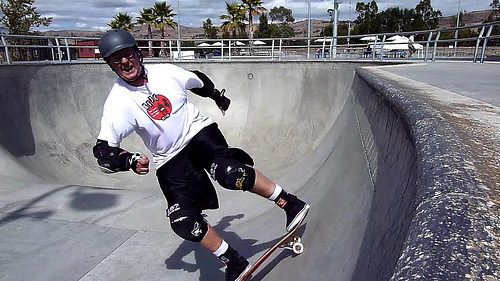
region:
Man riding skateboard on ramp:
[90, 28, 304, 280]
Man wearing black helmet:
[91, 25, 308, 279]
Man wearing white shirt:
[92, 25, 307, 279]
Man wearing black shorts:
[95, 27, 309, 279]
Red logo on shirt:
[136, 88, 177, 121]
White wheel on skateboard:
[292, 242, 306, 253]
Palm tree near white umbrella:
[240, 0, 266, 55]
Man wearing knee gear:
[83, 25, 318, 279]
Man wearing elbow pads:
[91, 27, 309, 279]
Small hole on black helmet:
[110, 25, 123, 35]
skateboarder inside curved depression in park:
[81, 20, 322, 272]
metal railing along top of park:
[5, 20, 490, 65]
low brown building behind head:
[67, 26, 157, 61]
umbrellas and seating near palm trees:
[180, 0, 420, 55]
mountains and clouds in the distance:
[130, 5, 335, 35]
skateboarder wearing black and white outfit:
[90, 60, 310, 275]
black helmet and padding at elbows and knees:
[90, 20, 255, 240]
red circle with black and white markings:
[137, 86, 172, 121]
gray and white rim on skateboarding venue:
[355, 60, 485, 276]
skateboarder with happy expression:
[101, 40, 144, 81]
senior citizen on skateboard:
[92, 25, 312, 278]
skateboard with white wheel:
[222, 203, 312, 280]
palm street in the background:
[105, 0, 270, 60]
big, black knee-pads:
[168, 158, 256, 242]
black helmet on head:
[95, 28, 145, 80]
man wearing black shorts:
[92, 28, 309, 280]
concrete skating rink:
[0, 55, 496, 275]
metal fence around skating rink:
[0, 20, 499, 62]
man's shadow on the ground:
[162, 213, 306, 279]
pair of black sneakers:
[221, 188, 311, 280]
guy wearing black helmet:
[79, 15, 313, 277]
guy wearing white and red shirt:
[79, 30, 324, 280]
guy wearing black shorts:
[66, 28, 320, 280]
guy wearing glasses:
[74, 15, 331, 276]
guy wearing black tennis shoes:
[86, 27, 322, 279]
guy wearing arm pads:
[74, 20, 327, 279]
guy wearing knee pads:
[66, 20, 315, 279]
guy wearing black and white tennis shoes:
[78, 26, 328, 278]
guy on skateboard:
[65, 21, 334, 279]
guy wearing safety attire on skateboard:
[66, 17, 341, 279]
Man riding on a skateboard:
[57, 22, 278, 264]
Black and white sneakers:
[252, 168, 313, 241]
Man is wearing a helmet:
[101, 18, 167, 88]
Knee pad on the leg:
[160, 208, 205, 250]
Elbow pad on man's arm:
[72, 130, 159, 207]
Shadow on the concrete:
[6, 143, 130, 248]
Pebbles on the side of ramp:
[407, 75, 469, 278]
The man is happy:
[100, 27, 140, 84]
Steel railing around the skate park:
[260, 13, 481, 78]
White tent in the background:
[357, 28, 421, 68]